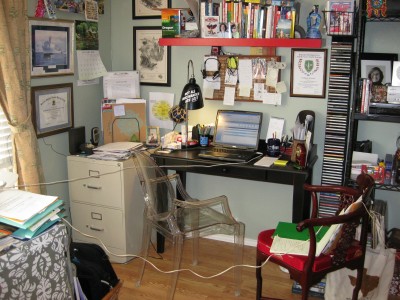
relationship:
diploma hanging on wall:
[31, 78, 77, 138] [19, 4, 109, 274]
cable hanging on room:
[14, 162, 251, 188] [4, 3, 396, 298]